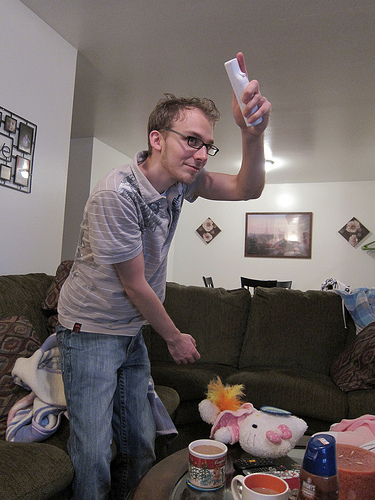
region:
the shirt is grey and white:
[63, 171, 178, 314]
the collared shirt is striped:
[74, 170, 272, 389]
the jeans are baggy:
[59, 343, 190, 492]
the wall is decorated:
[183, 205, 361, 277]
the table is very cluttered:
[214, 388, 350, 499]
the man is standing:
[56, 51, 269, 498]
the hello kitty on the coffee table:
[198, 374, 306, 458]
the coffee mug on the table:
[187, 438, 227, 487]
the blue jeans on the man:
[55, 317, 155, 498]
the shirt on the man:
[56, 150, 205, 336]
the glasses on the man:
[150, 124, 220, 156]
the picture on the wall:
[243, 211, 312, 258]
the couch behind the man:
[0, 272, 373, 498]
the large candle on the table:
[335, 443, 374, 499]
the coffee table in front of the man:
[131, 434, 312, 499]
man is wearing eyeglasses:
[139, 102, 217, 205]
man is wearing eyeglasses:
[148, 94, 217, 191]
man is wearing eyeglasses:
[139, 95, 231, 212]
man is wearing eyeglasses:
[155, 97, 231, 200]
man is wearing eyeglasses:
[141, 87, 226, 196]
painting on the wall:
[238, 202, 323, 271]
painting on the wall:
[232, 202, 319, 272]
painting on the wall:
[237, 205, 320, 266]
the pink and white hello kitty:
[197, 375, 307, 459]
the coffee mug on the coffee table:
[187, 438, 227, 488]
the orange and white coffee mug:
[231, 472, 289, 498]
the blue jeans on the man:
[56, 313, 157, 497]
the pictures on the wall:
[0, 104, 38, 193]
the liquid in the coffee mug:
[190, 443, 222, 455]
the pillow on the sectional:
[330, 321, 373, 389]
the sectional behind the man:
[0, 273, 373, 498]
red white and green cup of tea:
[171, 436, 240, 491]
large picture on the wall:
[240, 207, 321, 264]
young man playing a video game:
[58, 52, 258, 496]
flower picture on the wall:
[334, 210, 373, 252]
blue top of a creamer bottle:
[295, 435, 344, 499]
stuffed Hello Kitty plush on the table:
[188, 377, 308, 461]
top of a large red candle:
[335, 442, 373, 491]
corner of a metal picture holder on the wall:
[1, 140, 42, 200]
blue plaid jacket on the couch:
[333, 283, 373, 338]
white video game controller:
[216, 59, 265, 129]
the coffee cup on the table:
[187, 438, 227, 487]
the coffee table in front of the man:
[128, 435, 316, 498]